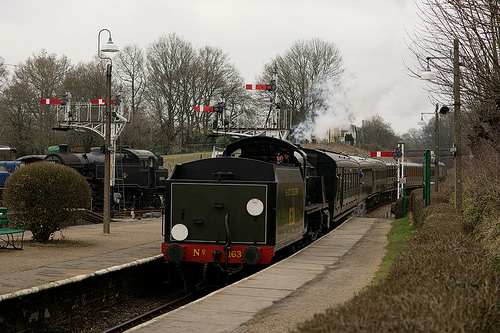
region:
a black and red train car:
[155, 127, 315, 276]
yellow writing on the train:
[188, 242, 208, 264]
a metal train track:
[106, 268, 224, 331]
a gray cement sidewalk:
[118, 210, 400, 332]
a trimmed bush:
[0, 157, 98, 243]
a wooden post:
[91, 59, 116, 236]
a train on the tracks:
[153, 131, 448, 279]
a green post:
[418, 147, 438, 206]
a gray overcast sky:
[1, 0, 498, 142]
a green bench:
[0, 202, 41, 258]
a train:
[187, 57, 313, 264]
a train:
[211, 35, 386, 295]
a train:
[223, 126, 304, 276]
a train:
[239, 155, 339, 310]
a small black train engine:
[154, 128, 305, 279]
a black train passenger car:
[299, 142, 363, 225]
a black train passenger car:
[356, 154, 384, 204]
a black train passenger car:
[385, 159, 402, 197]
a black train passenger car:
[403, 163, 429, 185]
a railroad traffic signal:
[42, 87, 119, 211]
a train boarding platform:
[0, 207, 175, 315]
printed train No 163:
[185, 244, 241, 261]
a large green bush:
[3, 161, 90, 242]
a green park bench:
[0, 207, 25, 251]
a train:
[217, 96, 284, 206]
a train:
[226, 77, 348, 244]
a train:
[157, 120, 283, 307]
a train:
[202, 202, 277, 322]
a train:
[215, 187, 310, 332]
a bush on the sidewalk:
[0, 158, 100, 250]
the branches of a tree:
[159, 46, 188, 78]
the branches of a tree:
[439, 6, 494, 34]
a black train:
[177, 141, 392, 249]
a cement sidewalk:
[202, 270, 284, 330]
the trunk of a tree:
[164, 100, 177, 144]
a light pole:
[93, 26, 128, 233]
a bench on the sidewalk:
[2, 206, 29, 249]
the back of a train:
[164, 151, 271, 261]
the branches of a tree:
[286, 54, 319, 106]